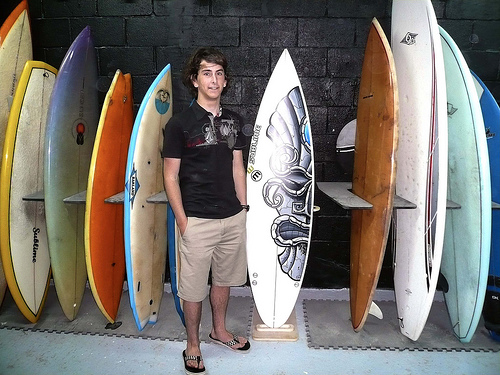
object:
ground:
[436, 127, 455, 157]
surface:
[260, 85, 306, 307]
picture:
[267, 153, 300, 247]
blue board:
[463, 60, 498, 116]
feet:
[185, 346, 203, 368]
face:
[198, 60, 225, 99]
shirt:
[162, 99, 247, 219]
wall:
[2, 0, 499, 289]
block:
[238, 18, 296, 43]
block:
[300, 17, 355, 48]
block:
[181, 15, 239, 45]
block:
[124, 17, 180, 47]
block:
[223, 44, 270, 75]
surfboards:
[1, 0, 499, 343]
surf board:
[245, 47, 314, 329]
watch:
[241, 204, 249, 211]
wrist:
[238, 203, 248, 212]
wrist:
[177, 217, 188, 227]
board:
[0, 0, 34, 304]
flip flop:
[182, 349, 206, 373]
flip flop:
[209, 333, 251, 351]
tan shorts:
[177, 209, 248, 302]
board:
[126, 63, 170, 331]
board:
[84, 68, 131, 322]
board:
[43, 25, 96, 321]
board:
[0, 60, 56, 321]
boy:
[162, 48, 251, 373]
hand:
[180, 228, 186, 237]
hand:
[242, 210, 247, 218]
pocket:
[181, 219, 202, 251]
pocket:
[234, 210, 246, 226]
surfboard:
[1, 2, 33, 168]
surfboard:
[348, 16, 400, 334]